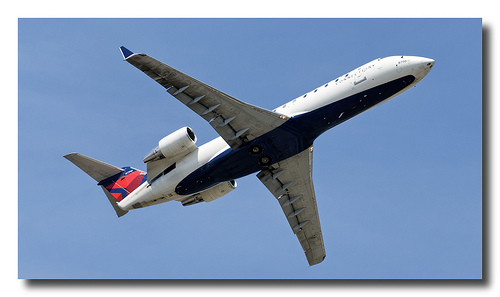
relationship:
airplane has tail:
[63, 45, 436, 265] [63, 151, 146, 217]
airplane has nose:
[63, 45, 436, 265] [384, 55, 435, 94]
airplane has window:
[63, 45, 436, 265] [344, 73, 350, 79]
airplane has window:
[63, 45, 436, 265] [334, 77, 339, 83]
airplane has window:
[63, 45, 436, 265] [324, 83, 329, 89]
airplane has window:
[63, 45, 436, 265] [314, 88, 319, 94]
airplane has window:
[63, 45, 436, 265] [302, 94, 307, 99]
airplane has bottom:
[63, 45, 436, 265] [174, 73, 415, 196]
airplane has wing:
[63, 45, 436, 265] [119, 45, 274, 147]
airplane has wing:
[63, 45, 436, 265] [256, 145, 326, 266]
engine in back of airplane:
[143, 126, 197, 163] [63, 45, 436, 265]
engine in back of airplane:
[182, 178, 237, 208] [63, 45, 436, 265]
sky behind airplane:
[19, 18, 483, 280] [63, 45, 436, 265]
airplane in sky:
[63, 45, 436, 265] [19, 18, 483, 280]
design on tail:
[98, 168, 147, 200] [63, 151, 146, 217]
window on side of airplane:
[344, 73, 350, 79] [63, 45, 436, 265]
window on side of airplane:
[334, 77, 339, 83] [63, 45, 436, 265]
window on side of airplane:
[324, 83, 329, 89] [63, 45, 436, 265]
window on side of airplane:
[314, 88, 319, 94] [63, 45, 436, 265]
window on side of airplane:
[302, 94, 307, 99] [63, 45, 436, 265]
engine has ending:
[182, 178, 237, 208] [181, 193, 204, 207]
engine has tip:
[143, 126, 197, 163] [143, 145, 164, 164]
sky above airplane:
[19, 18, 483, 280] [63, 45, 436, 265]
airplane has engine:
[63, 45, 436, 265] [143, 126, 197, 163]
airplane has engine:
[63, 45, 436, 265] [182, 178, 237, 208]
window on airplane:
[344, 73, 350, 79] [63, 45, 436, 265]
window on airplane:
[334, 77, 339, 83] [63, 45, 436, 265]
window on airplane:
[324, 83, 329, 89] [63, 45, 436, 265]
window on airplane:
[314, 88, 319, 94] [63, 45, 436, 265]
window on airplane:
[302, 94, 307, 99] [63, 45, 436, 265]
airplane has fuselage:
[63, 45, 436, 265] [118, 55, 435, 212]